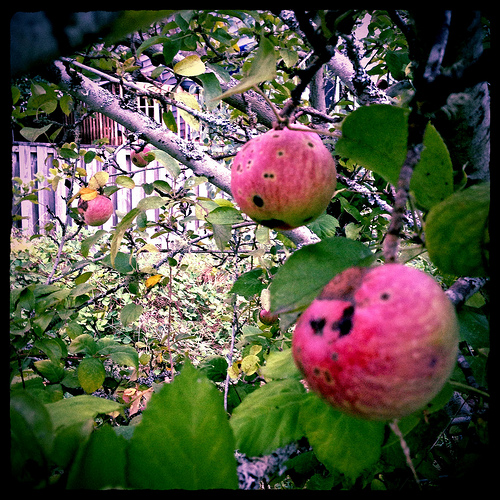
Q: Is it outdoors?
A: Yes, it is outdoors.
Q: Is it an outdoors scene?
A: Yes, it is outdoors.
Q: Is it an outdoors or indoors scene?
A: It is outdoors.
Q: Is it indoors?
A: No, it is outdoors.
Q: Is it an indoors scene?
A: No, it is outdoors.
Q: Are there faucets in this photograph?
A: No, there are no faucets.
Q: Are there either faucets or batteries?
A: No, there are no faucets or batteries.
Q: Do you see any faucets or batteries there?
A: No, there are no faucets or batteries.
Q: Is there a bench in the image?
A: No, there are no benches.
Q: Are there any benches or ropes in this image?
A: No, there are no benches or ropes.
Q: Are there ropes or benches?
A: No, there are no benches or ropes.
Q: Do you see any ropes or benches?
A: No, there are no benches or ropes.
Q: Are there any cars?
A: No, there are no cars.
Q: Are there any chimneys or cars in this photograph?
A: No, there are no cars or chimneys.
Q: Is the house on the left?
A: Yes, the house is on the left of the image.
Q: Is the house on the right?
A: No, the house is on the left of the image.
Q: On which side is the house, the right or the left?
A: The house is on the left of the image.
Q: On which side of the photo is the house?
A: The house is on the left of the image.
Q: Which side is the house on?
A: The house is on the left of the image.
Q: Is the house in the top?
A: Yes, the house is in the top of the image.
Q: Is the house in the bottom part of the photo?
A: No, the house is in the top of the image.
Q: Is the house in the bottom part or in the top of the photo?
A: The house is in the top of the image.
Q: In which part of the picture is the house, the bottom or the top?
A: The house is in the top of the image.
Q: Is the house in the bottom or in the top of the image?
A: The house is in the top of the image.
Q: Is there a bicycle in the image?
A: No, there are no bicycles.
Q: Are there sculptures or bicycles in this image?
A: No, there are no bicycles or sculptures.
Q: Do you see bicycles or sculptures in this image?
A: No, there are no bicycles or sculptures.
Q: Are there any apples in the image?
A: Yes, there are apples.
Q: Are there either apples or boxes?
A: Yes, there are apples.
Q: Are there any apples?
A: Yes, there is an apple.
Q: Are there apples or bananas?
A: Yes, there is an apple.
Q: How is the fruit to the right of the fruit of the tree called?
A: The fruit is an apple.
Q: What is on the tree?
A: The apple is on the tree.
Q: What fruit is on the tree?
A: The fruit is an apple.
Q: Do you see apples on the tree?
A: Yes, there is an apple on the tree.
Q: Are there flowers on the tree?
A: No, there is an apple on the tree.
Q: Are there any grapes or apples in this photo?
A: Yes, there is an apple.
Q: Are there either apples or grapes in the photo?
A: Yes, there is an apple.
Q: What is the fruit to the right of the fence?
A: The fruit is an apple.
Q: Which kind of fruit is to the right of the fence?
A: The fruit is an apple.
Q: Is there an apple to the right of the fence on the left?
A: Yes, there is an apple to the right of the fence.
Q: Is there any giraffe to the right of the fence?
A: No, there is an apple to the right of the fence.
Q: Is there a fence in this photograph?
A: Yes, there is a fence.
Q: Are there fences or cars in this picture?
A: Yes, there is a fence.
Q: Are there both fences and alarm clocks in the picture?
A: No, there is a fence but no alarm clocks.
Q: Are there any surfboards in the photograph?
A: No, there are no surfboards.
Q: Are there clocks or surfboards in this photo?
A: No, there are no surfboards or clocks.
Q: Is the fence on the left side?
A: Yes, the fence is on the left of the image.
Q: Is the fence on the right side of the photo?
A: No, the fence is on the left of the image.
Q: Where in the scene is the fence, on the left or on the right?
A: The fence is on the left of the image.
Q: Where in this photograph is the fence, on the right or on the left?
A: The fence is on the left of the image.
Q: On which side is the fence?
A: The fence is on the left of the image.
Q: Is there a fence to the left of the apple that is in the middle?
A: Yes, there is a fence to the left of the apple.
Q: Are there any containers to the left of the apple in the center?
A: No, there is a fence to the left of the apple.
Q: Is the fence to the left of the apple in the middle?
A: Yes, the fence is to the left of the apple.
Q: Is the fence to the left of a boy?
A: No, the fence is to the left of the apple.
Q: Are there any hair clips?
A: No, there are no hair clips.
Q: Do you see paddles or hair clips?
A: No, there are no hair clips or paddles.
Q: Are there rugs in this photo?
A: No, there are no rugs.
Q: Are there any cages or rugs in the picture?
A: No, there are no rugs or cages.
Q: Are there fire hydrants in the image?
A: No, there are no fire hydrants.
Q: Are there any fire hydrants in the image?
A: No, there are no fire hydrants.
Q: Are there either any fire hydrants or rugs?
A: No, there are no fire hydrants or rugs.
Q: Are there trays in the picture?
A: No, there are no trays.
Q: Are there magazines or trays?
A: No, there are no trays or magazines.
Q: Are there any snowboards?
A: No, there are no snowboards.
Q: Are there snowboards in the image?
A: No, there are no snowboards.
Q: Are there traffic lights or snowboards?
A: No, there are no snowboards or traffic lights.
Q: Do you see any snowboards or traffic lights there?
A: No, there are no snowboards or traffic lights.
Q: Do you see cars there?
A: No, there are no cars.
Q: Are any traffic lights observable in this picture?
A: No, there are no traffic lights.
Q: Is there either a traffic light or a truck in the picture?
A: No, there are no traffic lights or trucks.